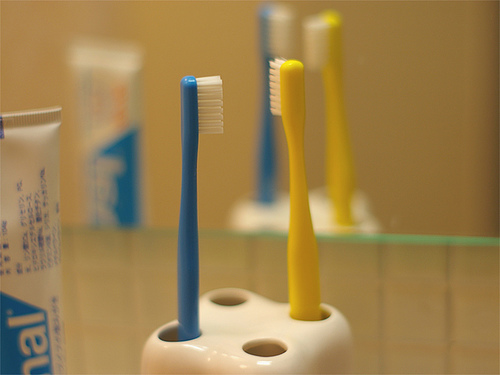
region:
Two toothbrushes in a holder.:
[125, 52, 360, 374]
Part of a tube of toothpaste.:
[1, 103, 77, 373]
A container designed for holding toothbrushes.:
[128, 271, 361, 372]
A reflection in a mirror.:
[68, 0, 383, 240]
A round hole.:
[242, 333, 291, 365]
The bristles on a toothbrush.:
[188, 72, 228, 140]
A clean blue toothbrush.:
[170, 70, 227, 340]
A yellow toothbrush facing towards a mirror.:
[263, 54, 337, 324]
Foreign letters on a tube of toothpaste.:
[0, 161, 72, 373]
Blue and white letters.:
[7, 310, 54, 374]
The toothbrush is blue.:
[157, 63, 244, 332]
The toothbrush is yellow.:
[260, 54, 336, 316]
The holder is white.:
[149, 278, 340, 373]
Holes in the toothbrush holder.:
[213, 262, 303, 362]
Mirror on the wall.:
[11, 9, 498, 321]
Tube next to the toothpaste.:
[2, 125, 89, 374]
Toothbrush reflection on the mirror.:
[236, 2, 363, 212]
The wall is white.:
[337, 255, 492, 370]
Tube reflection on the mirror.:
[64, 32, 156, 210]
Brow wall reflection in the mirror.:
[347, 14, 497, 196]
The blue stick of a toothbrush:
[178, 76, 201, 342]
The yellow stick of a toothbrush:
[281, 60, 326, 323]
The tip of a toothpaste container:
[0, 107, 62, 127]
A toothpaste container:
[0, 122, 70, 374]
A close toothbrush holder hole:
[238, 325, 296, 372]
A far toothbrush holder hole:
[207, 284, 258, 319]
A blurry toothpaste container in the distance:
[70, 44, 145, 228]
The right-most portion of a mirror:
[417, 0, 497, 241]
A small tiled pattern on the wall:
[85, 234, 136, 374]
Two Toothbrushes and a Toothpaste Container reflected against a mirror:
[0, 7, 492, 241]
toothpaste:
[2, 116, 69, 284]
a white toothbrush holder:
[200, 343, 267, 374]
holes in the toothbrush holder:
[247, 340, 282, 356]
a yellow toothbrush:
[282, 200, 344, 325]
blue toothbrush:
[165, 135, 217, 250]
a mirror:
[382, 123, 494, 239]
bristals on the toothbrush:
[197, 73, 228, 133]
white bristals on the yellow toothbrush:
[266, 60, 289, 117]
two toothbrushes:
[155, 70, 333, 297]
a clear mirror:
[376, 55, 497, 229]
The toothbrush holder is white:
[137, 285, 357, 373]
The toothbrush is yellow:
[263, 54, 323, 321]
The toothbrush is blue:
[171, 72, 227, 337]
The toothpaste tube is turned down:
[2, 103, 71, 373]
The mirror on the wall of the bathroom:
[63, 6, 499, 249]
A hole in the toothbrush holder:
[240, 335, 295, 365]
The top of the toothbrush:
[171, 62, 228, 196]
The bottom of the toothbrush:
[170, 210, 206, 341]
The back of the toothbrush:
[276, 59, 335, 316]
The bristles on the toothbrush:
[199, 71, 227, 138]